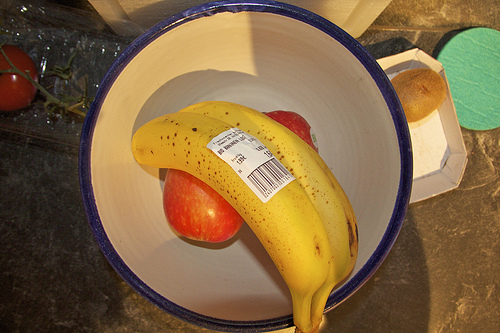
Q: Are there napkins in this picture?
A: No, there are no napkins.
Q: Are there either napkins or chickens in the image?
A: No, there are no napkins or chickens.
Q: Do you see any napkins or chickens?
A: No, there are no napkins or chickens.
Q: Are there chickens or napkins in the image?
A: No, there are no napkins or chickens.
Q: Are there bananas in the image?
A: Yes, there is a banana.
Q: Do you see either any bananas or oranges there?
A: Yes, there is a banana.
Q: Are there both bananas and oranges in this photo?
A: No, there is a banana but no oranges.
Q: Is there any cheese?
A: No, there is no cheese.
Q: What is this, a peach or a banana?
A: This is a banana.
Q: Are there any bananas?
A: Yes, there is a banana.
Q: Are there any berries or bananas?
A: Yes, there is a banana.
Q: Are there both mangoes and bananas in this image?
A: No, there is a banana but no mangoes.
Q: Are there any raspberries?
A: No, there are no raspberries.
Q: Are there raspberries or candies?
A: No, there are no raspberries or candies.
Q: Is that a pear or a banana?
A: That is a banana.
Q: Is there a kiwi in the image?
A: Yes, there is a kiwi.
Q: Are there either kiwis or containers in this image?
A: Yes, there is a kiwi.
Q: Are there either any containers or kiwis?
A: Yes, there is a kiwi.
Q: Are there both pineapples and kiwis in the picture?
A: No, there is a kiwi but no pineapples.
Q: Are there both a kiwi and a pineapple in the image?
A: No, there is a kiwi but no pineapples.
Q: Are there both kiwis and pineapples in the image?
A: No, there is a kiwi but no pineapples.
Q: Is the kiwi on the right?
A: Yes, the kiwi is on the right of the image.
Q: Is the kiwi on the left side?
A: No, the kiwi is on the right of the image.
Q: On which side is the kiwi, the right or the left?
A: The kiwi is on the right of the image.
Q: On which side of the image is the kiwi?
A: The kiwi is on the right of the image.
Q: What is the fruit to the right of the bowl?
A: The fruit is a kiwi.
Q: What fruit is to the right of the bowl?
A: The fruit is a kiwi.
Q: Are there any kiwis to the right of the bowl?
A: Yes, there is a kiwi to the right of the bowl.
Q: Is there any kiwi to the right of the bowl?
A: Yes, there is a kiwi to the right of the bowl.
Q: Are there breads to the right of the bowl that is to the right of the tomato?
A: No, there is a kiwi to the right of the bowl.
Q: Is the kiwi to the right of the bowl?
A: Yes, the kiwi is to the right of the bowl.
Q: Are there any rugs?
A: No, there are no rugs.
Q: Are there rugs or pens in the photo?
A: No, there are no rugs or pens.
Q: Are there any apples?
A: Yes, there is an apple.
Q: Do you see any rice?
A: No, there is no rice.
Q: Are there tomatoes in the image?
A: Yes, there is a tomato.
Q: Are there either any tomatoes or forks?
A: Yes, there is a tomato.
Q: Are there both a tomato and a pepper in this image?
A: No, there is a tomato but no peppers.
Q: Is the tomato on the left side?
A: Yes, the tomato is on the left of the image.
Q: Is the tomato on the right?
A: No, the tomato is on the left of the image.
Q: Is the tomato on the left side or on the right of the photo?
A: The tomato is on the left of the image.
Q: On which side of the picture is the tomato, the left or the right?
A: The tomato is on the left of the image.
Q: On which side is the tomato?
A: The tomato is on the left of the image.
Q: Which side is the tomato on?
A: The tomato is on the left of the image.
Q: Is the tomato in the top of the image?
A: Yes, the tomato is in the top of the image.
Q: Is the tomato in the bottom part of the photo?
A: No, the tomato is in the top of the image.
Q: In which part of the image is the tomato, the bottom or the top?
A: The tomato is in the top of the image.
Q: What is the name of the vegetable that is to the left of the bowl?
A: The vegetable is a tomato.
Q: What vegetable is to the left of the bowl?
A: The vegetable is a tomato.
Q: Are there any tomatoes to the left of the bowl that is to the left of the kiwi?
A: Yes, there is a tomato to the left of the bowl.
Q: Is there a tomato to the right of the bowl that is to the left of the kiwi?
A: No, the tomato is to the left of the bowl.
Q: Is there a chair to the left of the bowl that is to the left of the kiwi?
A: No, there is a tomato to the left of the bowl.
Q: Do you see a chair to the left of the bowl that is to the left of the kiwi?
A: No, there is a tomato to the left of the bowl.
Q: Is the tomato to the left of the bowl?
A: Yes, the tomato is to the left of the bowl.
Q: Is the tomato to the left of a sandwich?
A: No, the tomato is to the left of the bowl.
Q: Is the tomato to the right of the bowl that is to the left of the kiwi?
A: No, the tomato is to the left of the bowl.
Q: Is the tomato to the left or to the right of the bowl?
A: The tomato is to the left of the bowl.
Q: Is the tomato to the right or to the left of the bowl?
A: The tomato is to the left of the bowl.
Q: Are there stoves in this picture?
A: No, there are no stoves.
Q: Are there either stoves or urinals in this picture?
A: No, there are no stoves or urinals.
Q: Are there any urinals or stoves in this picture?
A: No, there are no stoves or urinals.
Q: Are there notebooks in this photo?
A: No, there are no notebooks.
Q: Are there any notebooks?
A: No, there are no notebooks.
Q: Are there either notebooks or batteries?
A: No, there are no notebooks or batteries.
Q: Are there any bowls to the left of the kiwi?
A: Yes, there is a bowl to the left of the kiwi.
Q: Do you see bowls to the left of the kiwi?
A: Yes, there is a bowl to the left of the kiwi.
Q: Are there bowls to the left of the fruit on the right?
A: Yes, there is a bowl to the left of the kiwi.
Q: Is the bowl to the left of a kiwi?
A: Yes, the bowl is to the left of a kiwi.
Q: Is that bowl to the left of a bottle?
A: No, the bowl is to the left of a kiwi.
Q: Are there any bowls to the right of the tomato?
A: Yes, there is a bowl to the right of the tomato.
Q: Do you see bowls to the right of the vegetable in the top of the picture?
A: Yes, there is a bowl to the right of the tomato.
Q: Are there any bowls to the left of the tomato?
A: No, the bowl is to the right of the tomato.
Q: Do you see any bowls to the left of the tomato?
A: No, the bowl is to the right of the tomato.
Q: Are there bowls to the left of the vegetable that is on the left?
A: No, the bowl is to the right of the tomato.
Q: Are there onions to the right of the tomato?
A: No, there is a bowl to the right of the tomato.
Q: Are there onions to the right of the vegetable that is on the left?
A: No, there is a bowl to the right of the tomato.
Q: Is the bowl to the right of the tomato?
A: Yes, the bowl is to the right of the tomato.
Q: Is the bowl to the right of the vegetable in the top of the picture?
A: Yes, the bowl is to the right of the tomato.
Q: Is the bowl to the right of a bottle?
A: No, the bowl is to the right of the tomato.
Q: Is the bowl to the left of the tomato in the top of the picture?
A: No, the bowl is to the right of the tomato.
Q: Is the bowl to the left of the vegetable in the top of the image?
A: No, the bowl is to the right of the tomato.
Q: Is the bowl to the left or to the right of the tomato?
A: The bowl is to the right of the tomato.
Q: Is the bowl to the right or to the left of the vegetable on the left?
A: The bowl is to the right of the tomato.